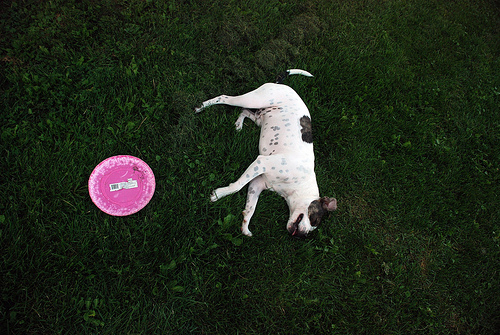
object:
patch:
[53, 33, 155, 107]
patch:
[383, 113, 440, 165]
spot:
[262, 147, 267, 152]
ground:
[76, 67, 494, 327]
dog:
[192, 69, 337, 237]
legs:
[193, 90, 259, 113]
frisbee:
[88, 155, 156, 216]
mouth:
[288, 213, 304, 234]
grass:
[2, 0, 499, 334]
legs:
[241, 175, 266, 236]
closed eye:
[314, 218, 318, 223]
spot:
[300, 114, 316, 143]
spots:
[274, 133, 279, 136]